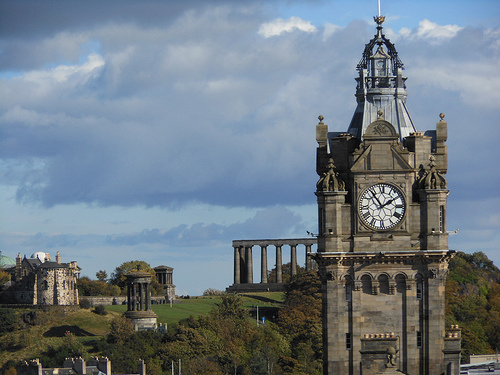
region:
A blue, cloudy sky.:
[5, 5, 491, 300]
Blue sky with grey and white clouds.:
[7, 3, 492, 290]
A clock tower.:
[281, 0, 476, 374]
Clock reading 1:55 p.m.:
[354, 172, 411, 234]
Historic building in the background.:
[6, 249, 86, 314]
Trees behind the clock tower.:
[124, 228, 495, 372]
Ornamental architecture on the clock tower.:
[316, 246, 452, 298]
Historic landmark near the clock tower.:
[223, 233, 320, 300]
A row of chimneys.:
[14, 356, 157, 373]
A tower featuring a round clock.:
[277, 5, 484, 374]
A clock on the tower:
[357, 183, 405, 229]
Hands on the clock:
[371, 190, 394, 209]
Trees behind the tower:
[106, 255, 496, 374]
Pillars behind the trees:
[231, 245, 315, 283]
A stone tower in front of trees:
[319, 3, 446, 374]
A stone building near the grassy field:
[15, 260, 77, 303]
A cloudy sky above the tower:
[0, 2, 497, 295]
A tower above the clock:
[347, 0, 416, 133]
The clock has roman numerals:
[359, 183, 405, 228]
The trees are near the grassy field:
[55, 253, 496, 373]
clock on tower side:
[359, 182, 404, 230]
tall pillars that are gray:
[222, 235, 321, 292]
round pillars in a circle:
[121, 272, 159, 339]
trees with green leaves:
[449, 248, 498, 356]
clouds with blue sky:
[1, 0, 498, 237]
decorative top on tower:
[351, 29, 421, 130]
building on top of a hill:
[2, 253, 89, 307]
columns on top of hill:
[214, 233, 317, 292]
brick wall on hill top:
[84, 293, 179, 307]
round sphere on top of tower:
[314, 112, 326, 125]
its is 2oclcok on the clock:
[348, 173, 433, 240]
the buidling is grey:
[311, 137, 462, 367]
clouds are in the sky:
[121, 96, 278, 203]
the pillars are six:
[233, 243, 311, 285]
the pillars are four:
[122, 280, 163, 311]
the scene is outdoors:
[6, 2, 482, 367]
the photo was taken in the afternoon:
[2, 0, 489, 370]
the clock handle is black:
[357, 191, 402, 221]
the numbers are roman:
[357, 185, 412, 231]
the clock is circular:
[355, 175, 423, 232]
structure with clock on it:
[285, 5, 487, 373]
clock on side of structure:
[352, 175, 410, 229]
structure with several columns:
[226, 228, 313, 287]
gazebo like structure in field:
[121, 258, 158, 328]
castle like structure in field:
[6, 263, 87, 303]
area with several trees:
[101, 325, 306, 372]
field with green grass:
[159, 307, 199, 319]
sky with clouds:
[12, 13, 309, 214]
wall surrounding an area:
[91, 295, 173, 307]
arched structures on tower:
[355, 269, 423, 296]